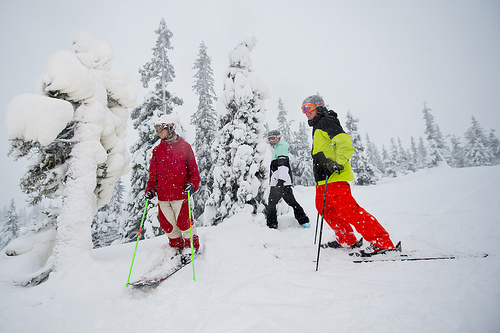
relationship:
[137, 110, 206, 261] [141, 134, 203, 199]
boy wearing jacket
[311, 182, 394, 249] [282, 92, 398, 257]
pants worn by woman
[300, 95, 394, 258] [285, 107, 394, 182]
skier wearing jacket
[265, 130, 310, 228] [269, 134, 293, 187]
man wearing jacket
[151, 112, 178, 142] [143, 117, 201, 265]
helmet worn by boy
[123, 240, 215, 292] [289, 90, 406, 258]
skis worn by skier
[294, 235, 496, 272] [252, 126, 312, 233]
skis worn by skier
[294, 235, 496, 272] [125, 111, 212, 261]
skis worn by skier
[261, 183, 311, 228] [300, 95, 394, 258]
black pants worn by skier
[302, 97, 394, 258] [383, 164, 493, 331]
skier standing on hill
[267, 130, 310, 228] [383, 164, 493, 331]
man standing on hill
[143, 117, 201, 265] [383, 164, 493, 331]
boy standing on hill